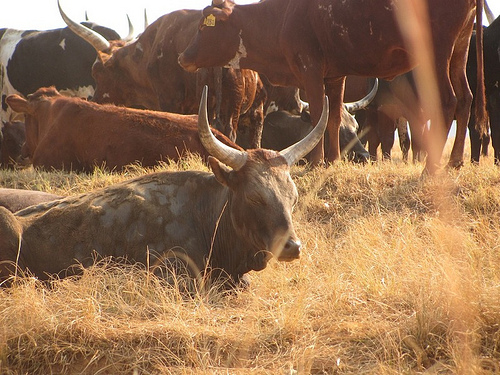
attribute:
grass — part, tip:
[231, 305, 268, 315]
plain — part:
[402, 201, 442, 221]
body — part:
[66, 101, 97, 110]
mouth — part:
[269, 245, 290, 255]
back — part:
[296, 2, 317, 9]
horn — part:
[79, 21, 104, 50]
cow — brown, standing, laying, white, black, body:
[197, 0, 471, 157]